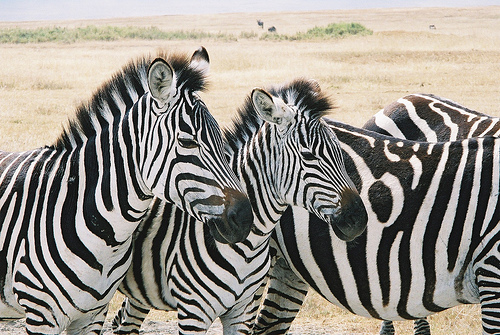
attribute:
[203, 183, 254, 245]
snout — black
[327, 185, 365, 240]
snout — black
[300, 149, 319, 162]
eye — small, black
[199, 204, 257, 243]
nose — black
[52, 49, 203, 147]
mane — white, black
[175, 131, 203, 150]
eye — black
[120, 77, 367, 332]
zebra — small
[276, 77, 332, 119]
skin — black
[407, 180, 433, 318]
skin — white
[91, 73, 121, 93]
hair — black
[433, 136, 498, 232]
stripes — white, black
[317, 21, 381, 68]
bushes — green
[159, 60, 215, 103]
ears — pointed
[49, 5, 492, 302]
zebras — striped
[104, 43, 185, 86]
ear — pointed